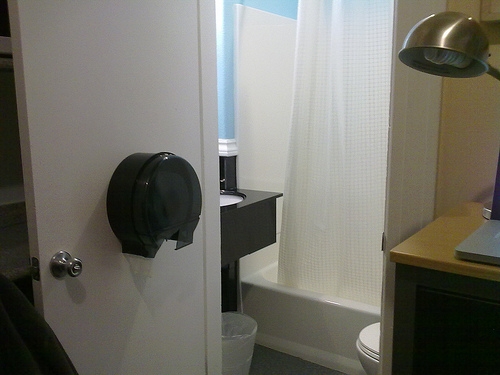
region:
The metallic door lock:
[51, 249, 83, 282]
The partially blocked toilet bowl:
[357, 317, 379, 370]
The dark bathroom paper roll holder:
[109, 153, 204, 258]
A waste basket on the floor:
[220, 311, 257, 373]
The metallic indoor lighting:
[397, 11, 499, 215]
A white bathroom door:
[8, 0, 218, 374]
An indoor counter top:
[394, 200, 499, 374]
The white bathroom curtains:
[217, 0, 385, 316]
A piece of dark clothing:
[0, 280, 83, 373]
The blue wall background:
[219, 1, 304, 161]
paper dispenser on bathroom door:
[101, 148, 202, 259]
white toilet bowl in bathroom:
[353, 317, 388, 374]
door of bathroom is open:
[12, 0, 402, 370]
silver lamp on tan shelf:
[397, 11, 499, 265]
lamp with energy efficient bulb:
[396, 9, 491, 84]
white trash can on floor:
[218, 306, 256, 373]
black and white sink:
[216, 177, 281, 310]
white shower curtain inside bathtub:
[280, 2, 390, 319]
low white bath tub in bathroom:
[241, 254, 381, 369]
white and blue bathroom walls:
[218, 3, 306, 191]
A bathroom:
[206, 3, 401, 373]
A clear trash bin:
[219, 310, 256, 371]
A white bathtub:
[235, 245, 391, 372]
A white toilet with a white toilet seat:
[343, 321, 390, 373]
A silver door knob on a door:
[40, 248, 91, 282]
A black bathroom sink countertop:
[216, 180, 282, 267]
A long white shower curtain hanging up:
[277, 1, 393, 321]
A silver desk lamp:
[392, 5, 494, 287]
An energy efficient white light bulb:
[420, 42, 474, 77]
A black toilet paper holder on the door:
[91, 139, 203, 287]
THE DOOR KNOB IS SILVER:
[42, 235, 83, 285]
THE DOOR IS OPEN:
[20, 0, 395, 372]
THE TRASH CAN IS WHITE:
[208, 305, 263, 372]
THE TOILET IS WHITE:
[342, 313, 383, 373]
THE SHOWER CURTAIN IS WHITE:
[271, 0, 383, 320]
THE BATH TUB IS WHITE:
[227, 253, 383, 373]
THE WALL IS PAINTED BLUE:
[215, 0, 305, 150]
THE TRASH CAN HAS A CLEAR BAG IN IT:
[203, 300, 265, 372]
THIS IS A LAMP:
[380, 10, 496, 103]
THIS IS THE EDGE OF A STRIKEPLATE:
[377, 230, 395, 259]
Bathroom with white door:
[8, 1, 219, 373]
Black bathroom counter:
[220, 181, 280, 263]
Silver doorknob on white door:
[49, 249, 81, 281]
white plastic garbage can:
[216, 311, 254, 373]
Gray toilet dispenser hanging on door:
[108, 148, 206, 258]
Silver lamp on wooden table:
[399, 12, 497, 219]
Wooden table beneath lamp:
[389, 192, 497, 372]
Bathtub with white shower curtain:
[276, 2, 393, 307]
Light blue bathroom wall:
[215, 0, 302, 137]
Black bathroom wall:
[215, 157, 240, 314]